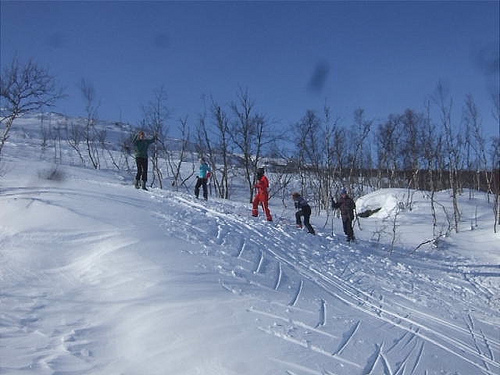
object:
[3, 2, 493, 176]
sky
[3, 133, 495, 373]
hill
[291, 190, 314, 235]
person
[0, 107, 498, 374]
mountain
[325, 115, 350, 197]
tree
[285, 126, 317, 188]
tree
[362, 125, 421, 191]
tree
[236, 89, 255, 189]
tree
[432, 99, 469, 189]
tree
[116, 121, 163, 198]
woman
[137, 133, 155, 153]
jacket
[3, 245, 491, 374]
snow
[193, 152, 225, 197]
coat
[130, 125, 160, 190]
person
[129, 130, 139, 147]
arm up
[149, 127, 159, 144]
arm up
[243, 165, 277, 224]
person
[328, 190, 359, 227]
snow jacket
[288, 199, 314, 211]
snow jacket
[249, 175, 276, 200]
snow jacket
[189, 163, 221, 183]
snow jacket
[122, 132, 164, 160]
snow jacket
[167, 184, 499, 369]
tracks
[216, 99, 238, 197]
trees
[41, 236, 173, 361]
sunlight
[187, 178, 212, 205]
pants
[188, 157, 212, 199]
girl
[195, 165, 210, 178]
coat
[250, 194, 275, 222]
red pants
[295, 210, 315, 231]
pants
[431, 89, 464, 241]
tree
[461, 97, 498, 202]
tree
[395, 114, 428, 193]
tree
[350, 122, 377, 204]
tree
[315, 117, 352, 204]
tree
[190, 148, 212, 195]
person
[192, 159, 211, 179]
jacket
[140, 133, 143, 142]
head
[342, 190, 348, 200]
head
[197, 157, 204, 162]
head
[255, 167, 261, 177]
head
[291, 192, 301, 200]
head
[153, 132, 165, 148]
arm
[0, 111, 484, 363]
ground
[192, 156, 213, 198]
person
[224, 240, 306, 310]
marks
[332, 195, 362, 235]
snowsuit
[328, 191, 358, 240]
person